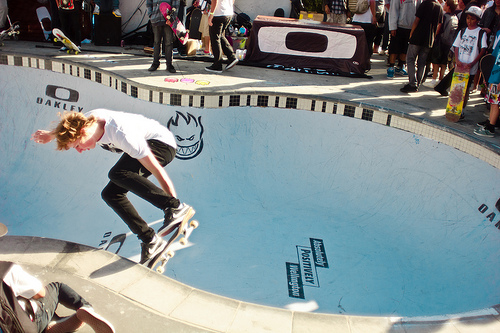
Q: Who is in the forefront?
A: Boy.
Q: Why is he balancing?
A: Trick.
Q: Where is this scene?
A: Skate park.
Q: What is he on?
A: Skateboard.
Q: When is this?
A: Late afternoon.